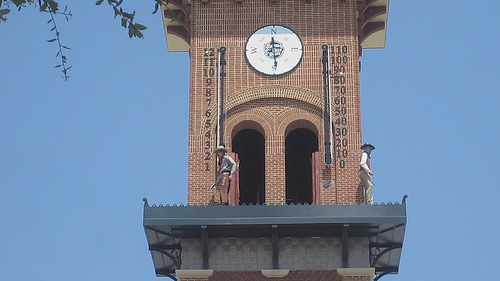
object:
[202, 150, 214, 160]
number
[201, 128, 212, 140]
number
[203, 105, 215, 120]
number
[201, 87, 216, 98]
number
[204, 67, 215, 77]
number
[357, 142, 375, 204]
cowboy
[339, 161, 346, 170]
0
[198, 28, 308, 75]
wall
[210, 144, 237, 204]
cowboy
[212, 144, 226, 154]
hat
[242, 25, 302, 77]
clock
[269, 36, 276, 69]
compass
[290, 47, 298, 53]
e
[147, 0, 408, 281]
tower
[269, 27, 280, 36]
n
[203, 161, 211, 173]
number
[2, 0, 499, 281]
sky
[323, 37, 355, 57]
wall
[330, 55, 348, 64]
number 100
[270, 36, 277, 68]
hand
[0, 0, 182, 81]
tree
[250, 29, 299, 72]
number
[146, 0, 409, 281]
building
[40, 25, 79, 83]
piece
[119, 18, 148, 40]
piece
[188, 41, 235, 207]
left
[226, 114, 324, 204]
archways